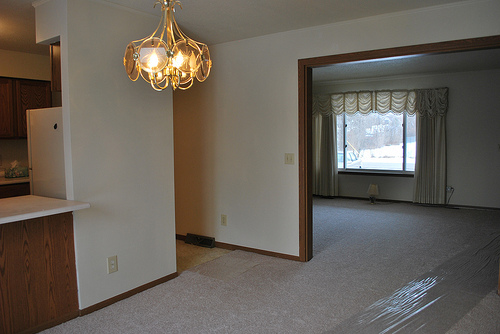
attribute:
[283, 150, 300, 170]
switch — white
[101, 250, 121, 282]
outlet — electrical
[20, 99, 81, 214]
refrigerator — white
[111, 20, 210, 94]
light — reflecting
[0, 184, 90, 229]
counter — white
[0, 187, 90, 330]
frame — wooden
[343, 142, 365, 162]
shrubs — green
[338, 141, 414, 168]
grass — green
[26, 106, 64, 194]
refrigerator — white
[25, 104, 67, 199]
fridge — white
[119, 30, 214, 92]
chandelier — golden, hanging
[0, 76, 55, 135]
cupboards — wood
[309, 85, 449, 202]
curtain — sheer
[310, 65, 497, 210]
wall — white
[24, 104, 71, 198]
fridge — side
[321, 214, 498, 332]
cover — PLASTIC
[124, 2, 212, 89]
chandelier — GOLDEN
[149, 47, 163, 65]
light — ON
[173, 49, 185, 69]
light — ON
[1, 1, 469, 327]
interior_of_house — empty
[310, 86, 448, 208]
curtains — white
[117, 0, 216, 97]
chandelier light — gold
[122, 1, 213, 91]
lamp — small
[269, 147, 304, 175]
light switch — white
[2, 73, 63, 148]
cabinets — wooden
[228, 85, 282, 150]
wall — white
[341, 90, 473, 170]
window — white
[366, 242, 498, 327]
floor — plastic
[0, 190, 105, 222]
counter top — WHITE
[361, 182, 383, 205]
lamp — small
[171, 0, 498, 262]
wall — white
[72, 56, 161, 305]
wall — WHITE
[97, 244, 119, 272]
plug — WHITE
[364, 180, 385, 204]
lamp — little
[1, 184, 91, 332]
bar — eating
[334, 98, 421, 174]
window — picture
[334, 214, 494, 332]
lining — plastic